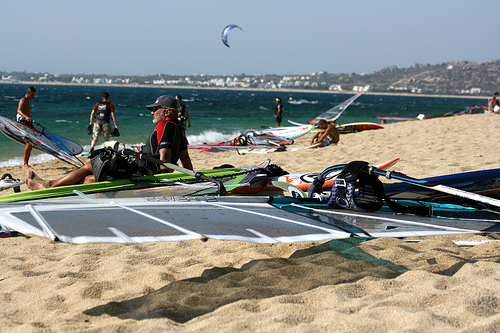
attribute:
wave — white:
[188, 130, 232, 144]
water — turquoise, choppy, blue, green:
[2, 81, 492, 165]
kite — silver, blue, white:
[218, 22, 243, 49]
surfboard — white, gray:
[4, 196, 496, 237]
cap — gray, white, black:
[146, 92, 182, 111]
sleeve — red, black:
[156, 120, 176, 150]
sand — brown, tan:
[0, 237, 496, 333]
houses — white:
[1, 69, 378, 91]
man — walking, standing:
[82, 91, 121, 151]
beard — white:
[152, 108, 167, 123]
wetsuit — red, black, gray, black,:
[137, 120, 190, 175]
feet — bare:
[24, 170, 51, 192]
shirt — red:
[91, 100, 114, 115]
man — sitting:
[309, 118, 342, 150]